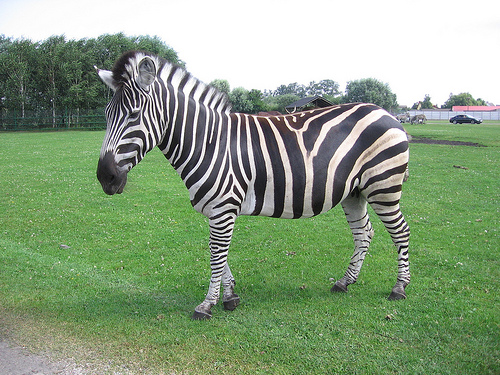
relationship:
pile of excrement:
[450, 159, 470, 178] [445, 159, 481, 184]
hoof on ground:
[380, 275, 421, 304] [4, 118, 499, 372]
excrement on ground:
[445, 159, 481, 184] [4, 118, 499, 372]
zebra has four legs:
[87, 43, 415, 323] [170, 196, 413, 324]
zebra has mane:
[87, 43, 415, 323] [112, 47, 271, 120]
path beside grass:
[3, 318, 148, 374] [49, 251, 165, 335]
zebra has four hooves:
[87, 43, 415, 323] [186, 270, 412, 323]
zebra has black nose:
[87, 43, 415, 323] [89, 151, 140, 198]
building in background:
[446, 101, 500, 126] [2, 35, 499, 135]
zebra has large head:
[87, 43, 415, 323] [90, 41, 172, 200]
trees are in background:
[3, 33, 188, 147] [2, 35, 499, 135]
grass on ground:
[49, 251, 165, 335] [4, 118, 499, 372]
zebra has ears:
[87, 43, 415, 323] [87, 57, 166, 98]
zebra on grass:
[87, 43, 415, 323] [49, 251, 165, 335]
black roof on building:
[282, 93, 341, 111] [283, 105, 337, 117]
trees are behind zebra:
[3, 33, 188, 147] [87, 43, 415, 323]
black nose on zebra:
[89, 151, 140, 198] [87, 43, 415, 323]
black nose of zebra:
[89, 151, 140, 198] [87, 43, 415, 323]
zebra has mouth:
[87, 43, 415, 323] [103, 177, 132, 196]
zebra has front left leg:
[87, 43, 415, 323] [190, 204, 235, 324]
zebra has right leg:
[87, 43, 415, 323] [206, 217, 250, 320]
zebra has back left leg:
[87, 43, 415, 323] [370, 169, 418, 315]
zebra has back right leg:
[87, 43, 415, 323] [324, 176, 376, 298]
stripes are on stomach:
[199, 122, 328, 196] [235, 134, 366, 222]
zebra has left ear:
[87, 43, 415, 323] [130, 50, 170, 96]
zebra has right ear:
[87, 43, 415, 323] [93, 63, 135, 101]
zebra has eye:
[87, 43, 415, 323] [124, 106, 151, 120]